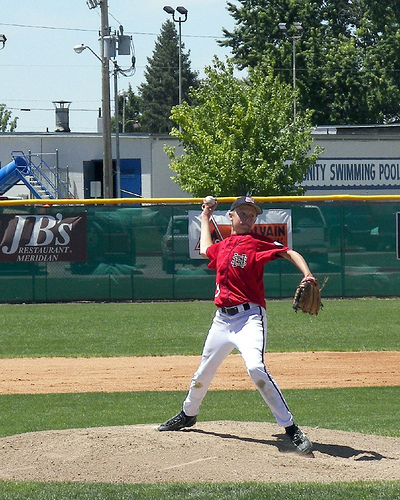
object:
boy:
[158, 191, 314, 455]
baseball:
[204, 193, 217, 205]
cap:
[229, 196, 263, 216]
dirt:
[1, 461, 399, 476]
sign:
[0, 215, 86, 264]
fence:
[0, 199, 396, 301]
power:
[79, 0, 135, 197]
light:
[74, 45, 85, 55]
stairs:
[17, 171, 56, 199]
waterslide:
[0, 147, 24, 200]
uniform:
[205, 241, 295, 305]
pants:
[177, 299, 297, 426]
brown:
[97, 2, 115, 202]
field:
[1, 301, 399, 352]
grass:
[0, 304, 399, 344]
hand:
[293, 280, 323, 315]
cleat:
[283, 426, 313, 457]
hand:
[196, 203, 213, 217]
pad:
[1, 195, 399, 205]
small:
[171, 66, 313, 194]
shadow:
[179, 421, 380, 465]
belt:
[213, 302, 254, 313]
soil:
[2, 358, 400, 387]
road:
[140, 249, 399, 274]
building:
[3, 125, 399, 198]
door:
[117, 160, 142, 198]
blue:
[1, 154, 17, 178]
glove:
[293, 280, 323, 313]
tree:
[164, 54, 317, 199]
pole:
[95, 46, 118, 210]